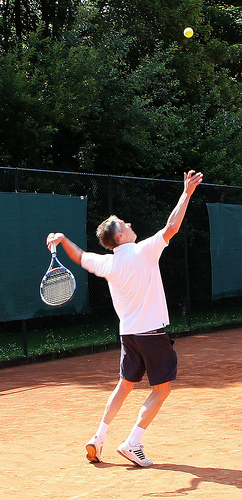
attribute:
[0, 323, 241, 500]
tennis court — brown, red clay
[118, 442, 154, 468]
tennis shoes — black, white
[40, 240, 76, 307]
tennis racket — blue, white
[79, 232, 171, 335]
shirt — white shirt, white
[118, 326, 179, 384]
shorts — black, dark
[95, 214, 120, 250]
hair — gray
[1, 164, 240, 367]
fence — green, chain link, large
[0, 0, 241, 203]
trees — green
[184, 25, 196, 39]
tennis ball — neon yellow, green, yellow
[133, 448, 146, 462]
lines — black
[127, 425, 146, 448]
socks — white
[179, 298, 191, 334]
weed — tall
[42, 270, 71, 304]
strings — white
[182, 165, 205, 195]
hand — raised